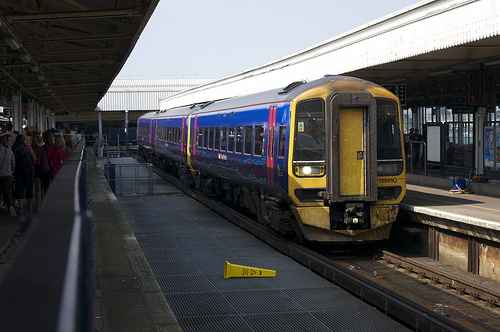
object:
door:
[333, 101, 370, 197]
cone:
[224, 260, 274, 279]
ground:
[93, 151, 419, 332]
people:
[0, 134, 20, 218]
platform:
[87, 127, 415, 331]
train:
[123, 69, 417, 250]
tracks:
[284, 242, 498, 331]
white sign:
[57, 145, 92, 332]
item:
[447, 172, 471, 195]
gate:
[104, 122, 138, 156]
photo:
[0, 0, 500, 330]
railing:
[0, 124, 96, 332]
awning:
[158, 0, 500, 112]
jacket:
[44, 144, 76, 177]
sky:
[92, 0, 433, 120]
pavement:
[0, 130, 80, 332]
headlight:
[300, 165, 314, 175]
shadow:
[403, 187, 486, 208]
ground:
[406, 179, 499, 240]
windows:
[449, 123, 455, 142]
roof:
[0, 0, 160, 113]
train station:
[0, 129, 415, 332]